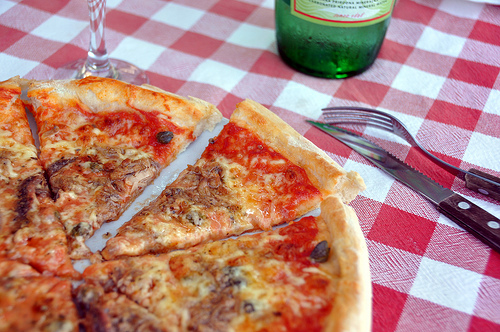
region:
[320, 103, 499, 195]
a fork on the table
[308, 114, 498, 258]
a knife on the table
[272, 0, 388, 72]
a green glass on the table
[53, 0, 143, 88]
the bottom of a wine glass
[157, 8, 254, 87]
the red checkered table cloth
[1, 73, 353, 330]
a pizza on a plate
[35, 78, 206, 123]
the crust of the pizza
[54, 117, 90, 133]
the cheese on the pizza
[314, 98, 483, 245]
utensils on the table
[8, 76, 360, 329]
a pizza with toppings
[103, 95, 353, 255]
a single slice of mushroom pizza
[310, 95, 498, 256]
a metal knife and fork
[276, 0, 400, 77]
the bottom of a green bottle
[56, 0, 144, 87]
the bottom of a glass cup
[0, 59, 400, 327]
a plate of mushroom pizza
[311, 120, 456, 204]
the metal blade of a knife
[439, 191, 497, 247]
the wooden handle of a knife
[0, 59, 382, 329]
a plate of delicious pizza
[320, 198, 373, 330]
the doughy crust of a pizza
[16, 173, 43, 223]
a mushroom on a pizza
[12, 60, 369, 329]
the pizza is on the table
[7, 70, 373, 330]
it is cut into pieces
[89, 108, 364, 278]
the pieces are triangular in shape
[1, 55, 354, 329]
it is red and brown in colour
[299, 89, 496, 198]
cultelery are on the table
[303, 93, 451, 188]
they have shiny surfaces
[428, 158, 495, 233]
they handles are brown in colour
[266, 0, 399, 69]
a green glass is on the table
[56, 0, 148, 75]
a glass is on the table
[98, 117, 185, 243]
the plate is white in colour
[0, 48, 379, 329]
A pizza in the foreground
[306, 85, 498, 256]
A knife and fork in the foreground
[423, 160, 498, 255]
Knife and fork have wooden handles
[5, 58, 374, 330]
Pizza is fully cooked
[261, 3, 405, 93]
A green colored bottle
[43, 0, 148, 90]
The bottom of a wine glass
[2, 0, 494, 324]
A red and white plaid colored cloth is over the table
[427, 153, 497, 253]
The wooden handles are dark brown in color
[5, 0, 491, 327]
Photo was taken in the daytime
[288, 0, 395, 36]
A label is on the green bottle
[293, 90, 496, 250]
steak knife and fork on the table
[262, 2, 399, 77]
green bottle on the table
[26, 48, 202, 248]
slice of pizza cut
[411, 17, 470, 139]
red and white checked table cloth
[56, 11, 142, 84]
glass stem on the table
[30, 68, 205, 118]
golden pizza crust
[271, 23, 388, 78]
bottle sweating on the table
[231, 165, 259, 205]
melted cheese on the pizza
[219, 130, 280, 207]
tomato sauce on the pizza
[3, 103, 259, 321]
pizza on the table